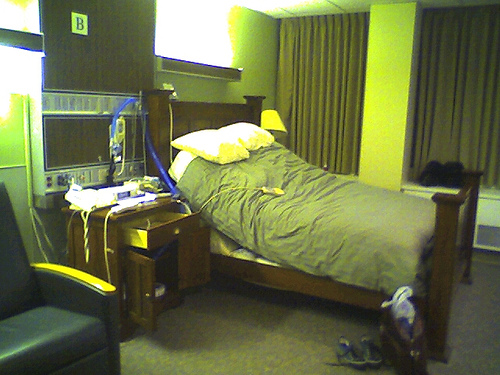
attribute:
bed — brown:
[142, 86, 484, 367]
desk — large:
[63, 180, 215, 342]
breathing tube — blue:
[142, 134, 183, 200]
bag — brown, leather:
[381, 283, 430, 374]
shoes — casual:
[331, 330, 384, 373]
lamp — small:
[0, 3, 47, 172]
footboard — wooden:
[412, 166, 481, 365]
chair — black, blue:
[2, 175, 121, 374]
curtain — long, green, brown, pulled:
[266, 16, 499, 193]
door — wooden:
[121, 247, 162, 333]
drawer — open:
[120, 210, 199, 247]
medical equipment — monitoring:
[105, 94, 181, 207]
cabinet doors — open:
[112, 208, 208, 335]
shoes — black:
[414, 152, 468, 191]